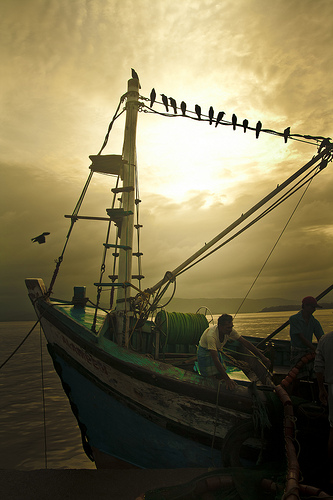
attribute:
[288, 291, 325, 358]
man — fisherman, working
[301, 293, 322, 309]
hat — red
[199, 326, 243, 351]
shirt — white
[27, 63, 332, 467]
boat — fishing, old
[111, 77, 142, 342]
mast — wooden, tall, white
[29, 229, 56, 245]
bird — landing, flying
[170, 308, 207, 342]
rope — green, spooled, spool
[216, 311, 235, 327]
hair — dark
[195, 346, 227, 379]
apron — green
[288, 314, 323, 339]
shirt — blue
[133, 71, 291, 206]
sun — shining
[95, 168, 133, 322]
ladder — rope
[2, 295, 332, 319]
mountains — distant